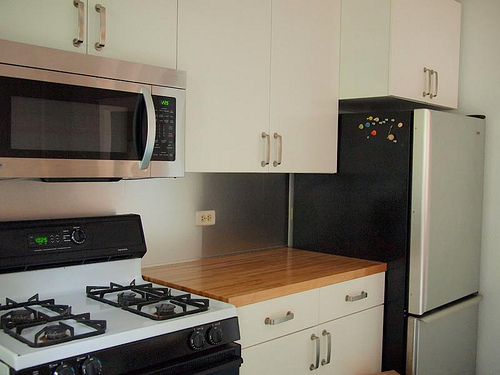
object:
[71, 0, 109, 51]
handles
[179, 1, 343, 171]
cabinet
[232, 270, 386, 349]
drawers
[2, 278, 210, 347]
stove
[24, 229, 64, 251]
clock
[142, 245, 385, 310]
butcher block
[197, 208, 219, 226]
outlet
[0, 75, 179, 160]
microwave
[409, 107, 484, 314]
refrigerator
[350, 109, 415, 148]
magnets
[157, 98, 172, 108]
numbers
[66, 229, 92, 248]
range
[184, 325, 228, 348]
knobs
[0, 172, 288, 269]
wall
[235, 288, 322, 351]
drawer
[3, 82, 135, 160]
door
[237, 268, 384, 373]
cabinets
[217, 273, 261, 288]
lines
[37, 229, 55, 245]
light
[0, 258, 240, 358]
stove top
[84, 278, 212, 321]
burners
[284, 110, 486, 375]
fridge